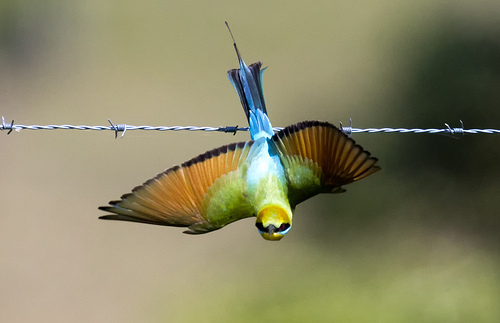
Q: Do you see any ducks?
A: No, there are no ducks.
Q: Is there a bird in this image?
A: Yes, there is a bird.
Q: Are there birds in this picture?
A: Yes, there is a bird.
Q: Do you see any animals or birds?
A: Yes, there is a bird.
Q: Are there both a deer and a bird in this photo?
A: No, there is a bird but no deer.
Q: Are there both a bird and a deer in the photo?
A: No, there is a bird but no deer.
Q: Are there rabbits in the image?
A: No, there are no rabbits.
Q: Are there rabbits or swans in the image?
A: No, there are no rabbits or swans.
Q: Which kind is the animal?
A: The animal is a bird.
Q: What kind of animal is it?
A: The animal is a bird.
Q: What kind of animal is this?
A: This is a bird.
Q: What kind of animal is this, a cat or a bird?
A: This is a bird.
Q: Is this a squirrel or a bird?
A: This is a bird.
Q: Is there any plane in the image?
A: No, there are no airplanes.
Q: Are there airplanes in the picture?
A: No, there are no airplanes.